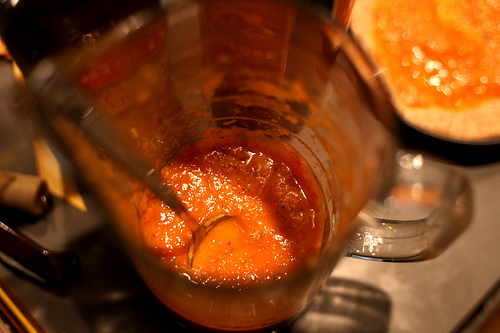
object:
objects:
[31, 137, 82, 198]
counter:
[0, 151, 500, 333]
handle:
[18, 57, 207, 234]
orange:
[403, 5, 434, 23]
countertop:
[352, 263, 462, 328]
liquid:
[113, 133, 329, 288]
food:
[347, 0, 499, 140]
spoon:
[40, 76, 237, 268]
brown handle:
[1, 170, 48, 215]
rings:
[132, 133, 334, 293]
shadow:
[294, 277, 393, 333]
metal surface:
[292, 146, 498, 333]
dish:
[134, 89, 364, 289]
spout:
[24, 45, 85, 134]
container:
[22, 0, 475, 333]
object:
[2, 193, 111, 301]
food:
[132, 137, 328, 288]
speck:
[225, 240, 231, 245]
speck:
[280, 203, 285, 207]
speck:
[239, 186, 245, 191]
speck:
[152, 232, 156, 237]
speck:
[299, 206, 304, 211]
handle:
[342, 147, 477, 266]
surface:
[0, 146, 500, 333]